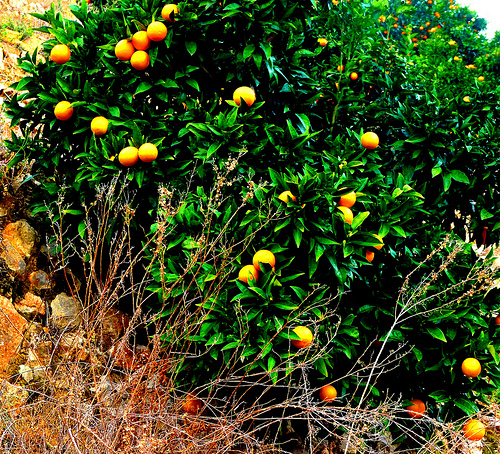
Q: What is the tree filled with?
A: Oranges.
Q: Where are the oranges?
A: On the tree.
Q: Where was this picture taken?
A: On a farm.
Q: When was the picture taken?
A: Summer.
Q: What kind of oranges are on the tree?
A: Ripe.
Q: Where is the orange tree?
A: In a field.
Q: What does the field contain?
A: Orange trees.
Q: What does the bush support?
A: Oranges.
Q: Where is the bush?
A: On the ground.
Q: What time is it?
A: Afternoon.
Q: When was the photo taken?
A: During the daytime.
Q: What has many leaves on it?
A: The tree.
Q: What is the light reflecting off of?
A: Green leaves.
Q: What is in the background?
A: Rocks.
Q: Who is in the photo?
A: No people.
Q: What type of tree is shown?
A: Orange.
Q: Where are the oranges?
A: On the tree.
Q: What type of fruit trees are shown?
A: Orange.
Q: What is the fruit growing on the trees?
A: Oranges.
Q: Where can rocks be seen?
A: Below orange tree.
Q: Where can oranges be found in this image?
A: On the tree.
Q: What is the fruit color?
A: Orange.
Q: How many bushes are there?
A: One.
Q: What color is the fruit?
A: Orange.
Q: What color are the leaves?
A: Green.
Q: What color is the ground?
A: Brown.